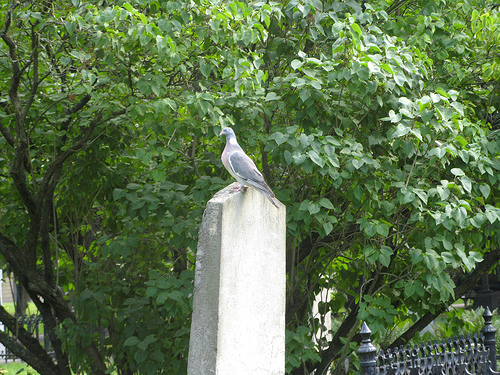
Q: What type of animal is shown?
A: Bird.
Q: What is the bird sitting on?
A: Monument.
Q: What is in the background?
A: Trees.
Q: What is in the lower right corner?
A: Fence.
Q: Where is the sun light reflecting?
A: Tree leaves.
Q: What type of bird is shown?
A: Pigeon.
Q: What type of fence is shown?
A: Wrought iron.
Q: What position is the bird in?
A: Standing.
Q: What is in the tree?
A: A branch.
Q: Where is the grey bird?
A: On top.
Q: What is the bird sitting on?
A: Gray pillar.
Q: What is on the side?
A: Metal fence.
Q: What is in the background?
A: Trees.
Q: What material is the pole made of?
A: Cement.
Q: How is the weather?
A: Sunny.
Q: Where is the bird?
A: Sitting outdoors.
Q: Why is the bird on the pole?
A: Resting.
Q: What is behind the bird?
A: A tree.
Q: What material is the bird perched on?
A: Cement.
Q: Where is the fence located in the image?
A: To the right of the bird.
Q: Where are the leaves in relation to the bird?
A: Behind it.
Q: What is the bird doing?
A: Standing still.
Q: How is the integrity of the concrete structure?
A: Chipped and dilapidated.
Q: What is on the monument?
A: Bird.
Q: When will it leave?
A: Soon.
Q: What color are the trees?
A: Green.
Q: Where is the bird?
A: On the block.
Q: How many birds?
A: 1.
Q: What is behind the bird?
A: Trees.